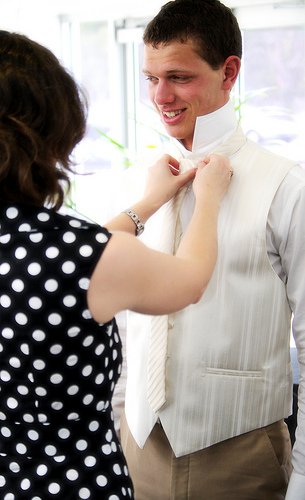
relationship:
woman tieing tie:
[1, 29, 232, 500] [122, 314, 164, 450]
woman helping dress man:
[1, 29, 232, 500] [140, 1, 303, 500]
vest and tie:
[124, 130, 296, 459] [122, 314, 164, 450]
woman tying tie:
[1, 29, 232, 500] [122, 314, 164, 450]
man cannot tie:
[140, 1, 303, 500] [122, 314, 164, 450]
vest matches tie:
[124, 130, 296, 459] [122, 314, 164, 450]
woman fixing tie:
[1, 29, 232, 500] [122, 314, 164, 450]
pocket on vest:
[208, 367, 267, 378] [124, 130, 296, 459]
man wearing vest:
[140, 1, 303, 500] [124, 130, 296, 459]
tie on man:
[122, 314, 164, 450] [140, 1, 303, 500]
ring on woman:
[227, 165, 235, 178] [1, 29, 232, 500]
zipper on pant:
[170, 453, 187, 498] [119, 415, 292, 500]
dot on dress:
[63, 260, 75, 275] [1, 208, 135, 500]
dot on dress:
[59, 294, 76, 308] [1, 208, 135, 500]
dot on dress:
[46, 246, 58, 257] [1, 208, 135, 500]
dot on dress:
[49, 373, 63, 385] [1, 208, 135, 500]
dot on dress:
[76, 244, 94, 256] [1, 208, 135, 500]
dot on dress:
[48, 310, 60, 324] [1, 208, 135, 500]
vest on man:
[124, 130, 296, 459] [140, 1, 303, 500]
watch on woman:
[125, 208, 144, 235] [1, 29, 232, 500]